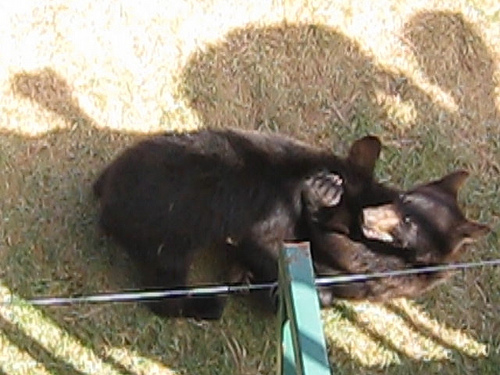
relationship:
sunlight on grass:
[258, 15, 499, 118] [36, 13, 494, 180]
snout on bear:
[358, 199, 398, 245] [94, 111, 476, 313]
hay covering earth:
[291, 25, 437, 110] [78, 38, 462, 108]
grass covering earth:
[13, 323, 153, 372] [78, 38, 462, 108]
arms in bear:
[269, 150, 348, 236] [94, 123, 491, 320]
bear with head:
[94, 123, 491, 320] [352, 148, 475, 312]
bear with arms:
[94, 123, 491, 320] [269, 150, 348, 236]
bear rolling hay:
[94, 111, 476, 313] [107, 42, 346, 106]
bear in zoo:
[94, 111, 476, 313] [5, 3, 473, 367]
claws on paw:
[299, 157, 354, 210] [196, 284, 233, 327]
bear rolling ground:
[94, 123, 491, 320] [74, 17, 393, 98]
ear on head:
[432, 160, 484, 229] [376, 157, 480, 293]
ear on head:
[351, 133, 388, 165] [315, 143, 411, 267]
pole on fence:
[278, 242, 330, 364] [2, 275, 290, 301]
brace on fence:
[267, 241, 330, 375] [275, 241, 332, 371]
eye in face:
[398, 193, 414, 238] [361, 189, 470, 256]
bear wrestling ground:
[94, 123, 491, 320] [112, 24, 388, 99]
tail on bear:
[81, 165, 128, 213] [94, 123, 491, 320]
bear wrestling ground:
[94, 123, 491, 320] [22, 20, 397, 124]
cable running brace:
[0, 258, 473, 320] [267, 241, 326, 372]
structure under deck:
[265, 318, 334, 365] [10, 264, 250, 310]